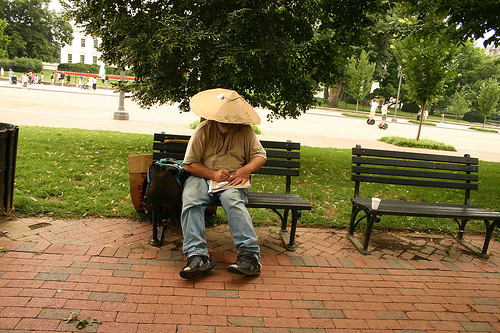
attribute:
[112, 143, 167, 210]
bag — large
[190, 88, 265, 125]
hat — conical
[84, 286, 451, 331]
bricks — red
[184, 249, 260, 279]
sandals — black